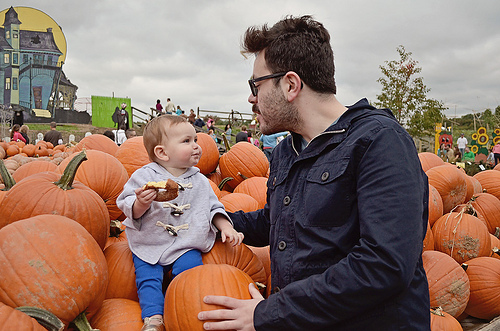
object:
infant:
[115, 114, 247, 330]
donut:
[138, 176, 181, 201]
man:
[192, 8, 431, 330]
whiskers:
[257, 79, 306, 137]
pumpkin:
[0, 300, 69, 330]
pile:
[0, 214, 109, 319]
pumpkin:
[82, 295, 147, 330]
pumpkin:
[1, 210, 112, 330]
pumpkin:
[99, 236, 144, 306]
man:
[164, 95, 177, 118]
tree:
[369, 37, 428, 135]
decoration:
[107, 103, 133, 132]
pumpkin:
[197, 227, 268, 293]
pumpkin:
[429, 304, 467, 331]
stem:
[70, 308, 98, 330]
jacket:
[213, 99, 433, 330]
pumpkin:
[161, 262, 262, 330]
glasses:
[246, 68, 305, 96]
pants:
[130, 246, 207, 323]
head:
[238, 9, 338, 135]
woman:
[18, 121, 32, 147]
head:
[19, 119, 32, 130]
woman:
[8, 119, 28, 146]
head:
[10, 122, 21, 132]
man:
[41, 118, 66, 147]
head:
[48, 119, 60, 132]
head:
[165, 95, 173, 105]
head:
[142, 111, 204, 168]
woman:
[173, 104, 184, 118]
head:
[175, 105, 182, 111]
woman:
[155, 98, 165, 118]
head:
[155, 97, 160, 106]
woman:
[185, 105, 197, 124]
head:
[189, 106, 195, 112]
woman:
[220, 119, 235, 147]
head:
[224, 121, 232, 133]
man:
[455, 128, 470, 155]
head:
[458, 130, 463, 138]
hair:
[240, 13, 335, 95]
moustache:
[250, 103, 264, 117]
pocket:
[294, 152, 360, 231]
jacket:
[115, 161, 233, 267]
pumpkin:
[418, 243, 474, 320]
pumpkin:
[459, 254, 499, 321]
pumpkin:
[429, 208, 496, 264]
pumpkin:
[456, 191, 500, 239]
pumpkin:
[425, 178, 446, 228]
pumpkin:
[418, 210, 437, 256]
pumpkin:
[422, 161, 471, 217]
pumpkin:
[408, 147, 450, 177]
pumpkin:
[0, 149, 113, 254]